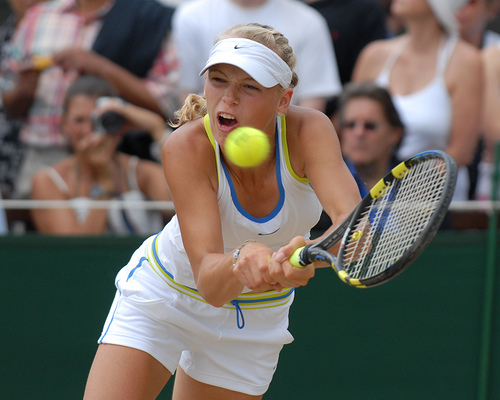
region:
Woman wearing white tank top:
[82, 24, 376, 399]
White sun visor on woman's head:
[197, 30, 297, 93]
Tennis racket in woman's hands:
[237, 150, 454, 290]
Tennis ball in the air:
[209, 115, 278, 173]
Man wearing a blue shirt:
[325, 82, 441, 228]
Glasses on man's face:
[334, 112, 382, 137]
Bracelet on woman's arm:
[225, 240, 247, 272]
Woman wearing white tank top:
[26, 86, 183, 241]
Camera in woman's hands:
[84, 94, 133, 144]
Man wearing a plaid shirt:
[6, 28, 186, 207]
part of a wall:
[462, 330, 489, 343]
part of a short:
[228, 353, 245, 371]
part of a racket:
[365, 261, 372, 278]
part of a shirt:
[271, 243, 285, 270]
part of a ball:
[258, 160, 264, 165]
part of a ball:
[238, 153, 244, 159]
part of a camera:
[83, 120, 113, 132]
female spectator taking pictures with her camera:
[29, 74, 176, 233]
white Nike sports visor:
[200, 37, 296, 91]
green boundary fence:
[0, 223, 498, 398]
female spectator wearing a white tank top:
[347, 0, 481, 201]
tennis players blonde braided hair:
[167, 21, 299, 128]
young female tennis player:
[81, 21, 373, 397]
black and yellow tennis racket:
[285, 147, 460, 292]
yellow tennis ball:
[220, 127, 273, 167]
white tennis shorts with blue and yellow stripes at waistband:
[94, 227, 296, 394]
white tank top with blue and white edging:
[156, 110, 326, 293]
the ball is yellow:
[221, 114, 273, 173]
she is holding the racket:
[268, 215, 334, 289]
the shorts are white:
[135, 284, 165, 335]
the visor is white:
[214, 43, 279, 80]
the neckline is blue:
[251, 207, 281, 227]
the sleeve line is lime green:
[283, 146, 305, 188]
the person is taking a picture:
[61, 75, 151, 164]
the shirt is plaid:
[38, 21, 62, 40]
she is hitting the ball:
[221, 116, 412, 286]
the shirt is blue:
[347, 157, 370, 198]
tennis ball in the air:
[221, 123, 268, 166]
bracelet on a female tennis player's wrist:
[231, 243, 251, 271]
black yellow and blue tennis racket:
[285, 145, 457, 290]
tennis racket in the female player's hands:
[285, 149, 457, 291]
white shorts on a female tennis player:
[95, 236, 298, 396]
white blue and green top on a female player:
[155, 110, 326, 306]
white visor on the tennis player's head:
[198, 35, 293, 88]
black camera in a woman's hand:
[90, 95, 127, 144]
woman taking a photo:
[28, 73, 178, 233]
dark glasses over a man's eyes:
[335, 119, 382, 131]